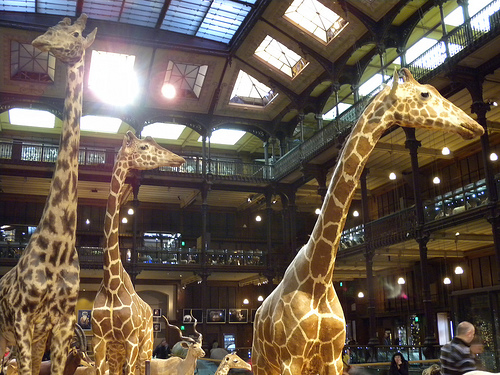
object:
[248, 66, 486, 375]
giraffe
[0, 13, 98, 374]
statue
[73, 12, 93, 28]
horns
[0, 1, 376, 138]
ceiling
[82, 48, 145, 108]
skylight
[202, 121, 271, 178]
arch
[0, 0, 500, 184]
third floor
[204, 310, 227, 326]
pictures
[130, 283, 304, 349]
wall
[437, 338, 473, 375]
shirt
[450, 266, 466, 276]
lights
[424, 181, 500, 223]
railing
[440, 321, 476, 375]
man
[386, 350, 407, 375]
woman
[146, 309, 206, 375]
deer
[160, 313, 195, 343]
antlers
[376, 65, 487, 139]
head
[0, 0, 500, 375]
building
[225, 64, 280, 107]
window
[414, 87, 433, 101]
eye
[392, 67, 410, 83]
ear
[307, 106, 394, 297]
neck